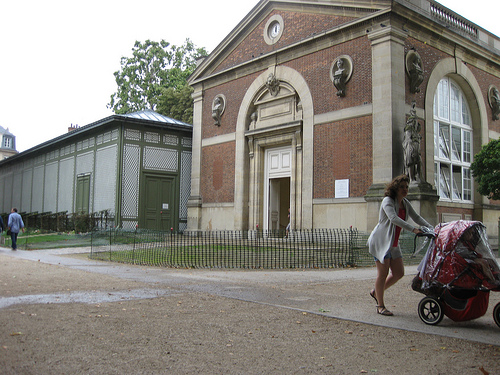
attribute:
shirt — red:
[391, 204, 406, 249]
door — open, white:
[265, 180, 281, 239]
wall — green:
[214, 121, 260, 174]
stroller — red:
[408, 216, 499, 333]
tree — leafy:
[104, 31, 209, 123]